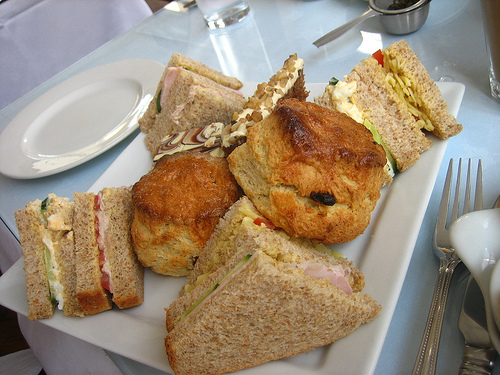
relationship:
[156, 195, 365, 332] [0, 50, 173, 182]
sandwich on plate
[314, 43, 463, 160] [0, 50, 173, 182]
sandwich on plate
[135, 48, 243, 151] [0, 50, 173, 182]
sandwich on plate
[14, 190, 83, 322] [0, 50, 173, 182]
sandwich on plate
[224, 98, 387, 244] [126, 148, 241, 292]
biscuit next to biscuit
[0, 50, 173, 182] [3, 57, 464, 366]
plate next to plate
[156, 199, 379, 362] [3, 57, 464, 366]
sandwich on plate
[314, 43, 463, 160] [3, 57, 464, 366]
sandwich on plate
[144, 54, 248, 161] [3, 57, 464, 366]
sandwich on plate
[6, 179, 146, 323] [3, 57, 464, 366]
sandwich on plate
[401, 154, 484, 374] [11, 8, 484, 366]
fork on table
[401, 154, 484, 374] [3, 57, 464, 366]
fork beside plate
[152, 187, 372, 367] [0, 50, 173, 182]
sandwich on plate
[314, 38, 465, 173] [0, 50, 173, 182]
sandwich on plate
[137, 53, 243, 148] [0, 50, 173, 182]
sandwich on plate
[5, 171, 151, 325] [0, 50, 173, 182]
sandwich on plate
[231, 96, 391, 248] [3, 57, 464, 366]
biscuit on plate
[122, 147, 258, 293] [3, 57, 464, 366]
biscuit on plate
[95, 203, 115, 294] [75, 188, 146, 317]
meat on sandwich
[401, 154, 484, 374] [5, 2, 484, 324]
fork resting on table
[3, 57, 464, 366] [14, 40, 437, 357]
plate with food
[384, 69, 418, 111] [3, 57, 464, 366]
pastry on plate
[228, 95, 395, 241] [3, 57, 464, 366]
pastry on plate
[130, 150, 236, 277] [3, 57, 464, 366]
biscuit on center of plate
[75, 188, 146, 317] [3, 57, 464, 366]
sandwich on plate